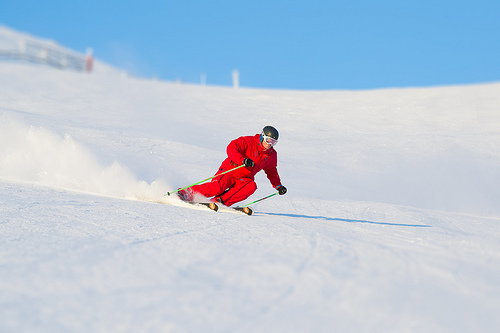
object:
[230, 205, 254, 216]
ski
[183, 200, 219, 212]
ski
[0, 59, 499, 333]
snow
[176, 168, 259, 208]
pants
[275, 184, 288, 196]
gloves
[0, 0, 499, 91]
sky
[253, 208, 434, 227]
shadow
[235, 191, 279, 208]
snow pole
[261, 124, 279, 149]
helmet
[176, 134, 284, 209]
jumpsuit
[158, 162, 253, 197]
pole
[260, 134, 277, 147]
goggles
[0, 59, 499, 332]
hill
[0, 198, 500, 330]
snow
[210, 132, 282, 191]
clothes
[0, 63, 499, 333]
ski slope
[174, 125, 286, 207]
he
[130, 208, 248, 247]
ski marks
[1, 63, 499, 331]
ground